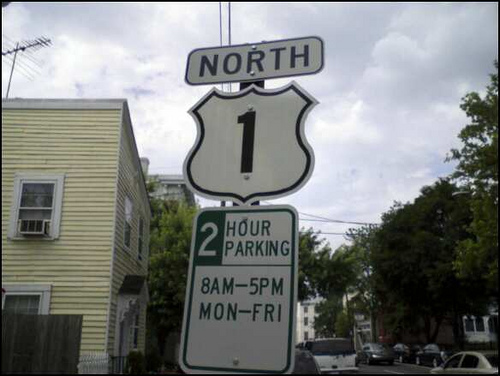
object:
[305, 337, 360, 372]
suv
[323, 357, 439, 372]
street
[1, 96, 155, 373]
building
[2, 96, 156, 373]
siding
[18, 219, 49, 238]
ac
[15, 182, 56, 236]
window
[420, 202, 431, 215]
ground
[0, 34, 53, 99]
antenna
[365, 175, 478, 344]
tree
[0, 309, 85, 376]
brown fence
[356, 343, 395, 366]
car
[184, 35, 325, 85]
sign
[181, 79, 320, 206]
sign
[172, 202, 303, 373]
sign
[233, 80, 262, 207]
post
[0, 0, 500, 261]
clouds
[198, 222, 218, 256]
number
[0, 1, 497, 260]
sky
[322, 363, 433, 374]
road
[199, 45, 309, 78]
lettering